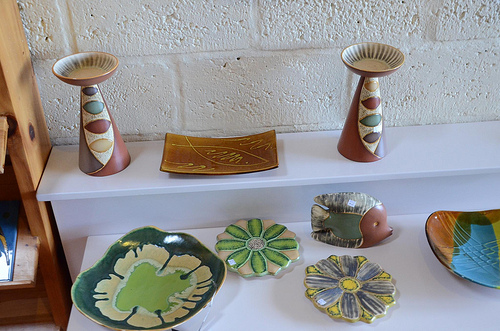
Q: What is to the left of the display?
A: Shelf.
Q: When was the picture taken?
A: Daytime.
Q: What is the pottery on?
A: Display.